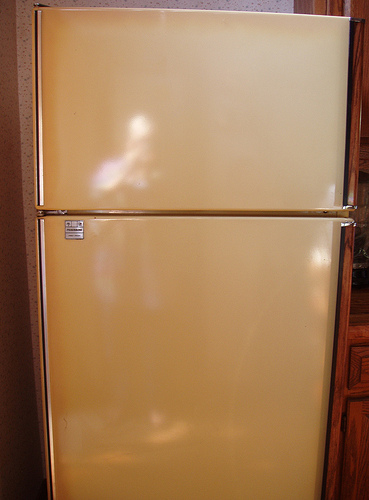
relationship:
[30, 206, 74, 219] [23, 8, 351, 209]
hinge between doors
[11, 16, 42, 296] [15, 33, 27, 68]
wall covering with dots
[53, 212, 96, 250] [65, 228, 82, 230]
plate with information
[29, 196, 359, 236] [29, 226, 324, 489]
space between doors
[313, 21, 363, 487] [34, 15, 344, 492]
cabinets next to refrigerator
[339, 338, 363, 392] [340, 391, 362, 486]
drawer and door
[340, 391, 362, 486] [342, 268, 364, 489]
door on cabinet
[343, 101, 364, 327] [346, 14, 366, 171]
storage space in cabinet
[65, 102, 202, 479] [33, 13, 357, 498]
reflection on refrigerator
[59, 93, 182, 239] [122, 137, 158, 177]
man holding camera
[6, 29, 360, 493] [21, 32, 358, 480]
refrigerator in a kitchen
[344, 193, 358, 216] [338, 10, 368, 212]
hinges and trim